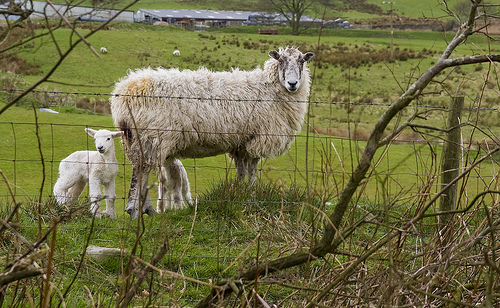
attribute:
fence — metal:
[0, 88, 435, 278]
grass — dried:
[195, 195, 374, 237]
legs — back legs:
[120, 130, 200, 222]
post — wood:
[437, 89, 468, 246]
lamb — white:
[28, 133, 170, 235]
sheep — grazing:
[80, 19, 354, 251]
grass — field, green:
[12, 26, 498, 223]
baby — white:
[52, 144, 181, 232]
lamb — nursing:
[46, 121, 174, 209]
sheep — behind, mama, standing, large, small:
[107, 45, 313, 217]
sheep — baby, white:
[96, 35, 343, 218]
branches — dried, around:
[262, 123, 494, 290]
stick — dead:
[199, 0, 499, 305]